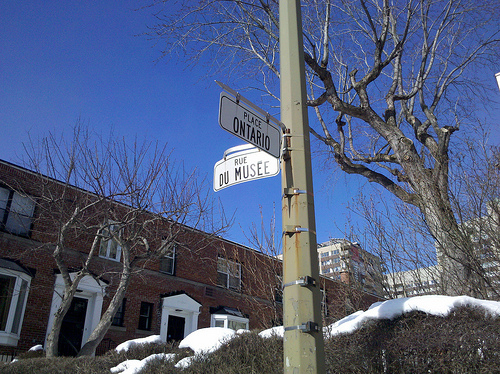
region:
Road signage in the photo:
[200, 87, 288, 176]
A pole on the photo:
[272, 192, 326, 339]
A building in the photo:
[90, 202, 246, 297]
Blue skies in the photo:
[71, 77, 199, 172]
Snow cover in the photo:
[380, 295, 460, 318]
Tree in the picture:
[352, 54, 492, 243]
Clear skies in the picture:
[68, 49, 182, 136]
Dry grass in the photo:
[355, 325, 459, 372]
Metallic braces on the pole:
[281, 258, 330, 291]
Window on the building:
[3, 192, 31, 232]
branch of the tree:
[401, 118, 443, 168]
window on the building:
[212, 260, 243, 292]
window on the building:
[152, 243, 171, 278]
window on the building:
[99, 223, 120, 255]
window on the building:
[0, 195, 40, 232]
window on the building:
[163, 309, 185, 350]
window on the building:
[325, 248, 345, 268]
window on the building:
[13, 217, 30, 239]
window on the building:
[9, 193, 28, 213]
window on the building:
[1, 282, 36, 334]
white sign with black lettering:
[208, 94, 291, 159]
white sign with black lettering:
[206, 141, 281, 196]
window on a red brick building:
[0, 188, 44, 239]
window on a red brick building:
[96, 218, 126, 260]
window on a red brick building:
[158, 238, 178, 276]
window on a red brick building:
[212, 255, 244, 287]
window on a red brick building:
[134, 298, 157, 338]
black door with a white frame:
[40, 268, 110, 364]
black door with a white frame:
[151, 286, 201, 348]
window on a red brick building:
[0, 263, 35, 350]